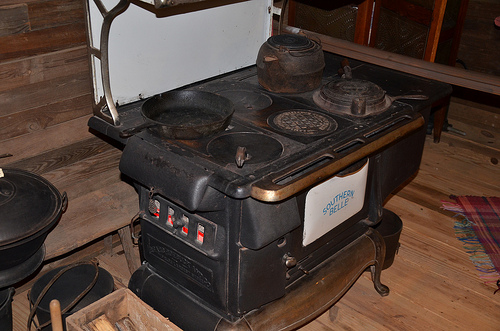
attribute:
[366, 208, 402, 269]
bucket — black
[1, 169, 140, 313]
bench — brown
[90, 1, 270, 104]
screen — white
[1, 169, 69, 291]
pan — black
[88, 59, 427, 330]
stove — black, antique, rusty, made of cast iron, wood, old, iron, wood burning, expensive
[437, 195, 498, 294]
rug — plaid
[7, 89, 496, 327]
floor — wood, wooden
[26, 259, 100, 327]
tong — old, made of metal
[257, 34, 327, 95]
tea kettle — rusty, black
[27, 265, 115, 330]
pot — large, made of cast iron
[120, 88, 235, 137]
frying pan — iron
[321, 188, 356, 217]
words — blue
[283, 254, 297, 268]
knob — brass